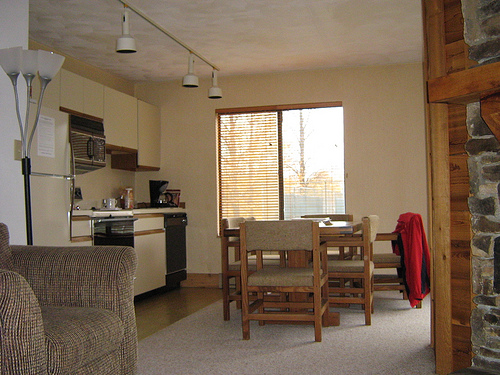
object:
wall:
[134, 63, 435, 288]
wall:
[28, 35, 136, 304]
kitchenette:
[27, 96, 189, 304]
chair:
[0, 218, 139, 375]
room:
[1, 1, 499, 375]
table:
[222, 220, 364, 329]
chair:
[351, 210, 426, 310]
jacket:
[390, 213, 430, 308]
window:
[216, 101, 348, 240]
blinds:
[219, 110, 280, 230]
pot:
[150, 180, 171, 207]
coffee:
[157, 200, 167, 204]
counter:
[70, 206, 185, 217]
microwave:
[70, 131, 106, 168]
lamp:
[0, 45, 67, 246]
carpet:
[137, 288, 431, 375]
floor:
[134, 286, 436, 375]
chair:
[239, 220, 328, 343]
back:
[244, 222, 314, 251]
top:
[239, 219, 320, 277]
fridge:
[27, 102, 77, 247]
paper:
[37, 114, 56, 158]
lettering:
[39, 117, 54, 156]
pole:
[21, 157, 35, 246]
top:
[21, 155, 32, 176]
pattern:
[2, 318, 43, 375]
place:
[466, 104, 498, 373]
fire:
[493, 237, 500, 293]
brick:
[467, 196, 498, 217]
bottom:
[241, 276, 323, 341]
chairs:
[307, 214, 377, 326]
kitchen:
[28, 2, 433, 374]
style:
[111, 1, 225, 101]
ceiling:
[30, 1, 425, 85]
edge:
[464, 103, 478, 373]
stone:
[465, 135, 499, 157]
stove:
[70, 205, 136, 248]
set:
[217, 212, 428, 341]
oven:
[92, 215, 138, 248]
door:
[94, 219, 135, 248]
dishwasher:
[163, 213, 189, 290]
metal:
[165, 227, 187, 276]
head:
[0, 46, 25, 161]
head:
[18, 49, 40, 159]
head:
[27, 50, 67, 158]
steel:
[70, 114, 107, 174]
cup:
[104, 198, 119, 209]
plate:
[99, 208, 122, 212]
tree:
[222, 112, 276, 222]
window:
[220, 112, 283, 227]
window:
[280, 106, 346, 222]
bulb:
[0, 46, 23, 77]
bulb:
[20, 50, 40, 78]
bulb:
[35, 49, 64, 83]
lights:
[207, 69, 222, 100]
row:
[114, 0, 223, 100]